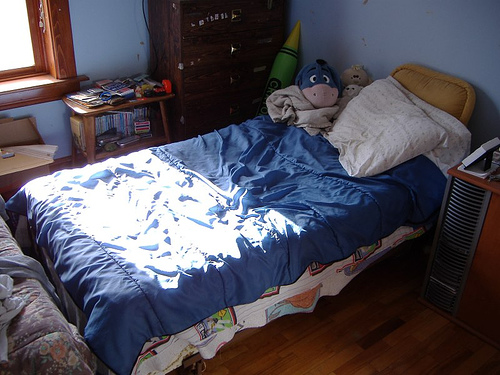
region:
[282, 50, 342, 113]
a stuffed eeyore doll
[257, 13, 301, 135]
a large yellow crayon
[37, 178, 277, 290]
a bright sun shine on bed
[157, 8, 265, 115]
a brown dresser in room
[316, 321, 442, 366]
hardwood flooring under bed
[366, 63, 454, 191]
pillows on the bed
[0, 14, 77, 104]
a brown window sill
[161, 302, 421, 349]
bed sheets on a bed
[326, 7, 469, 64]
blue paint on wall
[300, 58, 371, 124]
teddy bears on the bed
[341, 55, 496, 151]
pillows on the bed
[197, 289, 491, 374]
the floor is wooden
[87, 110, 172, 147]
books on the bookshelf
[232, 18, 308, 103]
the crayon in the corner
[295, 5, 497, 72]
the wall is blue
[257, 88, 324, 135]
the towel on the bed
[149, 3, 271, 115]
the dresser in the corner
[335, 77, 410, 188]
pillowcase on the pillow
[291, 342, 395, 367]
the flooring is wooden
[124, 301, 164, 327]
the sheets are blue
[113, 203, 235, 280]
sun reflecting on sheets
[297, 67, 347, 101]
eeyore stuffed animal on bed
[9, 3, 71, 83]
window on the wall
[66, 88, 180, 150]
desk on the side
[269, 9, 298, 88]
oversized crayon near wall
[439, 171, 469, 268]
vent next to bed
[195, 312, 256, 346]
sheets hanging off bed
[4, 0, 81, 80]
window of the room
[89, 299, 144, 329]
the comforter is blue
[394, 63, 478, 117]
the headboard is small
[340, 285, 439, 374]
the flooring is wooden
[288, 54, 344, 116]
stuffed Eeyore lying on the bed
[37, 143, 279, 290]
light shining on the bed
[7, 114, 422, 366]
blue cover on the bed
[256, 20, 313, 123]
large crayon leaning against the wall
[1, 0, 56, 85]
light coming in the window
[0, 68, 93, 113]
wooden window sill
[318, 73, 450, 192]
pillow on the bed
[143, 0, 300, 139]
dark brown dresser in the corner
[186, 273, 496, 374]
hardwood floor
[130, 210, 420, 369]
sheets hanging over the bed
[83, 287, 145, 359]
a blue comforter covering a bed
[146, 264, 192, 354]
a blue comforter covering a bed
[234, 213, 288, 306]
a blue comforter covering a bed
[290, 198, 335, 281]
a blue comforter covering a bed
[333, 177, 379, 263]
a blue comforter covering a bed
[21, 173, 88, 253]
a blue comforter covering a bed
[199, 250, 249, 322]
a blue mattress covering a bed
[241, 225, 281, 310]
a blue mattress covering a bed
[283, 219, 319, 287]
a blue mattress covering a bed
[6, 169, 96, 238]
a blue mattress covering a bed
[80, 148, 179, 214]
a blue mattress covering a bed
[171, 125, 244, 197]
a blue mattress covering a bed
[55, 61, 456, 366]
A single sized bed.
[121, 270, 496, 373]
Brown hardwood floors.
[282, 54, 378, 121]
Stuffed animals at the top of a bed.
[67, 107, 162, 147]
A row of books.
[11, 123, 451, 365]
A blue comforter on a bed.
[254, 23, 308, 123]
A yellow large crayon.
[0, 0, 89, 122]
A brown wooden window frame.